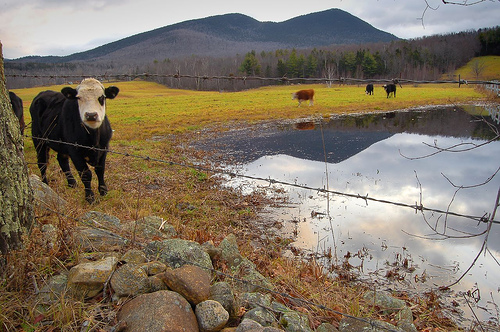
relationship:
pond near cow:
[202, 104, 496, 304] [27, 73, 125, 203]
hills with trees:
[2, 6, 416, 86] [246, 46, 393, 78]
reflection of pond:
[204, 131, 494, 314] [184, 100, 494, 298]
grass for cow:
[120, 75, 296, 129] [363, 77, 373, 93]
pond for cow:
[173, 108, 496, 162] [29, 73, 119, 209]